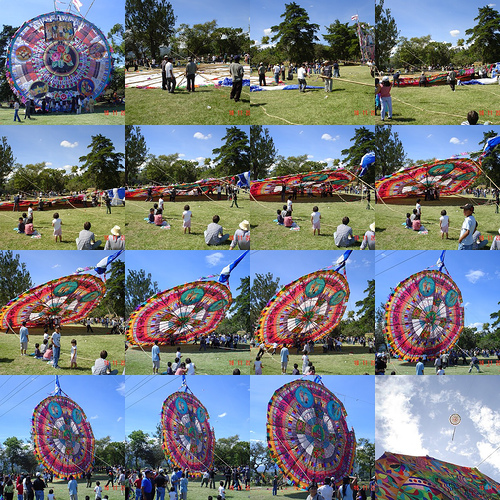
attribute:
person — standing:
[19, 322, 30, 356]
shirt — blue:
[17, 327, 29, 344]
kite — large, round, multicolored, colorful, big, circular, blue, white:
[5, 12, 112, 112]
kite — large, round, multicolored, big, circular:
[125, 251, 251, 346]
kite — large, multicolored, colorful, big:
[374, 135, 499, 204]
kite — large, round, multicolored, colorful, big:
[254, 251, 354, 349]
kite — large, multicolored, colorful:
[383, 250, 466, 364]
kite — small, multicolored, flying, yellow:
[449, 413, 461, 441]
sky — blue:
[374, 375, 499, 483]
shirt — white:
[49, 329, 63, 347]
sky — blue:
[1, 1, 126, 69]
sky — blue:
[126, 1, 250, 37]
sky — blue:
[250, 1, 376, 49]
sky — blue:
[376, 0, 499, 52]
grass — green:
[123, 87, 249, 125]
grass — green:
[252, 63, 374, 125]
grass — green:
[374, 353, 499, 373]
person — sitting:
[103, 225, 126, 249]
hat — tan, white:
[110, 225, 121, 237]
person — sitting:
[228, 219, 252, 251]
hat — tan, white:
[238, 220, 250, 231]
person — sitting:
[358, 220, 377, 249]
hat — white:
[369, 221, 375, 231]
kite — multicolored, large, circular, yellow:
[0, 251, 126, 329]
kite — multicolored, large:
[266, 377, 357, 490]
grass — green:
[378, 72, 499, 123]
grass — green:
[0, 208, 128, 250]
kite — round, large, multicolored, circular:
[160, 374, 217, 475]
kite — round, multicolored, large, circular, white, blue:
[29, 376, 98, 480]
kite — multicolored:
[375, 452, 499, 499]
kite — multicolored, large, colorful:
[250, 167, 360, 196]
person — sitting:
[89, 351, 114, 375]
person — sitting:
[412, 215, 423, 232]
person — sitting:
[331, 217, 357, 247]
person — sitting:
[202, 214, 228, 246]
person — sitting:
[74, 222, 101, 249]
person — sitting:
[280, 205, 288, 216]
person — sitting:
[154, 208, 165, 225]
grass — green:
[125, 199, 250, 251]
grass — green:
[249, 195, 377, 251]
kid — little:
[438, 209, 450, 240]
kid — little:
[306, 205, 326, 235]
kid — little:
[179, 206, 194, 234]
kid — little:
[49, 213, 66, 242]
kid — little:
[68, 340, 81, 369]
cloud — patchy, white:
[60, 140, 79, 151]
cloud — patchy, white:
[194, 132, 212, 143]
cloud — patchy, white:
[318, 134, 339, 145]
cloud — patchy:
[448, 137, 469, 148]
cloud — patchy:
[204, 252, 225, 268]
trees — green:
[125, 126, 250, 185]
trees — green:
[252, 126, 376, 186]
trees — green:
[250, 3, 375, 66]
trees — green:
[376, 0, 500, 72]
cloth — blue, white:
[251, 86, 324, 92]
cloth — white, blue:
[460, 78, 500, 86]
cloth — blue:
[219, 78, 252, 86]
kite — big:
[126, 177, 226, 200]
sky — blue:
[1, 126, 126, 173]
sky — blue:
[129, 127, 251, 168]